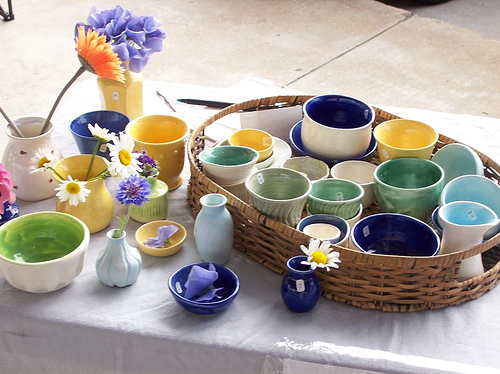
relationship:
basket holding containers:
[187, 92, 500, 313] [198, 92, 496, 281]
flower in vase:
[115, 175, 151, 206] [93, 225, 143, 288]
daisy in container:
[298, 236, 342, 273] [279, 254, 321, 314]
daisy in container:
[26, 146, 67, 174] [50, 152, 115, 236]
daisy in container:
[54, 174, 92, 207] [50, 152, 115, 236]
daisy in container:
[84, 120, 117, 145] [50, 152, 115, 236]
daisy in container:
[105, 130, 145, 179] [50, 152, 115, 236]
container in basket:
[227, 127, 275, 163] [187, 92, 500, 313]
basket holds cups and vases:
[187, 92, 500, 313] [198, 92, 496, 281]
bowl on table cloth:
[168, 261, 242, 316] [2, 71, 499, 373]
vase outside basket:
[193, 191, 236, 267] [187, 92, 500, 313]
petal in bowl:
[145, 225, 177, 248] [135, 218, 190, 259]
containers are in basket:
[198, 92, 496, 281] [187, 92, 500, 313]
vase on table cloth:
[93, 225, 143, 288] [2, 71, 499, 373]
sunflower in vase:
[75, 25, 128, 85] [1, 115, 66, 202]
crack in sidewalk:
[279, 10, 414, 89] [1, 0, 500, 115]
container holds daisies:
[50, 152, 115, 236] [26, 121, 143, 205]